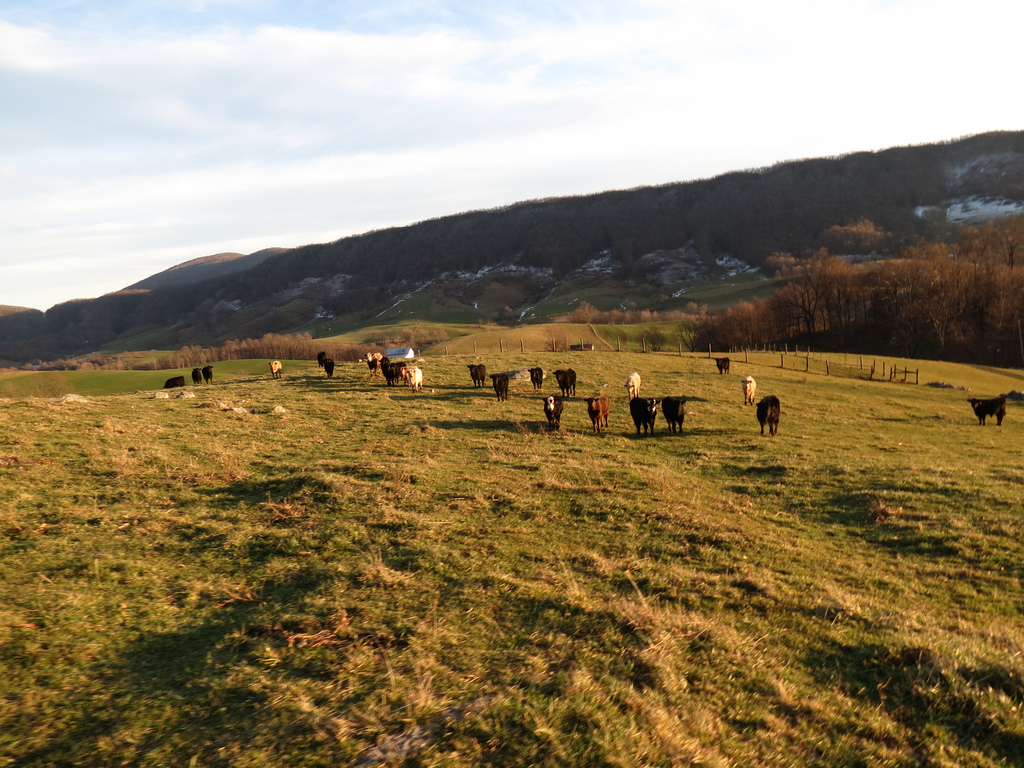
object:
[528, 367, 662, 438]
cows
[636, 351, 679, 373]
hillside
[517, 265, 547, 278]
snow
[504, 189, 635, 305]
hill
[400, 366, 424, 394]
cow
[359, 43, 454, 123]
clouds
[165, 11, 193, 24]
sky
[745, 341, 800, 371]
fence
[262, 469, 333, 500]
grass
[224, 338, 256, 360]
brush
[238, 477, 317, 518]
shadows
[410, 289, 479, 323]
trees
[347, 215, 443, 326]
hills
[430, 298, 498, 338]
vegetation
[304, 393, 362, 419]
pasture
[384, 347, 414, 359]
building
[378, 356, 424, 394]
cattle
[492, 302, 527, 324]
treeline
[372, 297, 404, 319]
ravine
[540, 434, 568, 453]
manure